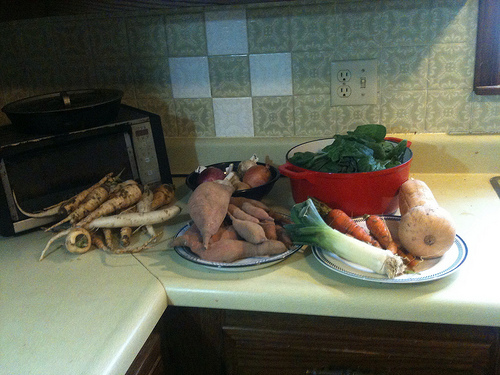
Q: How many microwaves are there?
A: 1.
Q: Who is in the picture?
A: No one.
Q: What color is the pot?
A: Red.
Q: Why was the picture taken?
A: To capture the vegetables.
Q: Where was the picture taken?
A: On a kitchen counter.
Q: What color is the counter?
A: Beige.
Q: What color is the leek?
A: Green and white.